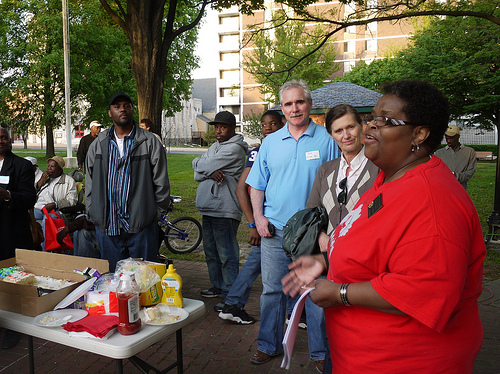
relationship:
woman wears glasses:
[267, 79, 488, 374] [364, 110, 431, 137]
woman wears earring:
[267, 79, 488, 374] [408, 142, 423, 157]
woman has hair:
[267, 79, 488, 374] [377, 74, 449, 153]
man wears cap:
[83, 89, 177, 280] [100, 84, 135, 107]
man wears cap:
[187, 111, 250, 301] [203, 100, 241, 135]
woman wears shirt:
[267, 79, 488, 374] [321, 156, 486, 374]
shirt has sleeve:
[321, 156, 486, 374] [367, 223, 460, 334]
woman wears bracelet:
[267, 79, 488, 374] [336, 281, 360, 310]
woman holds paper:
[267, 79, 488, 374] [275, 279, 324, 373]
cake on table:
[1, 248, 113, 318] [1, 296, 210, 373]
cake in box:
[1, 248, 113, 318] [0, 248, 117, 318]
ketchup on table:
[112, 273, 147, 337] [1, 296, 210, 373]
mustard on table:
[161, 264, 188, 313] [1, 296, 210, 373]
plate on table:
[34, 302, 87, 330] [1, 296, 210, 373]